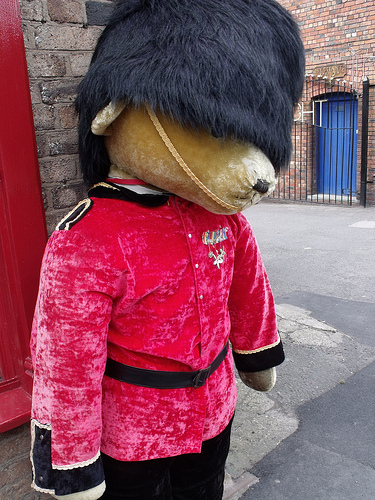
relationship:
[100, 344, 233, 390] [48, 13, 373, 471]
belt on bear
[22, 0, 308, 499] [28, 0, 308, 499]
bear dressed like bear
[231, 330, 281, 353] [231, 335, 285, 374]
trim on cuff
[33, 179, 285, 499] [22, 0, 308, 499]
jacket on bear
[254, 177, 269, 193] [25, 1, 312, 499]
nose on teddy bear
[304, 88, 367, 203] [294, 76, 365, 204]
door behind bars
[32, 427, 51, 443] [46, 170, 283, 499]
snap on cuff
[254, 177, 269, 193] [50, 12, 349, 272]
nose of bear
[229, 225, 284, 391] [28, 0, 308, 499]
arm of bear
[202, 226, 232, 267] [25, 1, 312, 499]
medal on teddy bear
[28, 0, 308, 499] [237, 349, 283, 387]
bear with paws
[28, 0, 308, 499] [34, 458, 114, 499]
bear with paws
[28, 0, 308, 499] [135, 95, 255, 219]
bear with strap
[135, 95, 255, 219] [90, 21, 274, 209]
strap across face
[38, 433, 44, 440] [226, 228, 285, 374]
button on sleeve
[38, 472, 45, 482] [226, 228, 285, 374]
button on sleeve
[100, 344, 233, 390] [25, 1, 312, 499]
belt on teddy bear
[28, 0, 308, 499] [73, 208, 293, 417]
bear in uniform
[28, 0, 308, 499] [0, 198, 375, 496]
bear on pavement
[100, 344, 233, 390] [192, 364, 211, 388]
belt with plastic clasp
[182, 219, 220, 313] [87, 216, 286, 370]
metal buttons on side of cuff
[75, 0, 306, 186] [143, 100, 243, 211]
hat has strap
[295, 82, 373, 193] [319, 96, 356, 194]
fence in front of door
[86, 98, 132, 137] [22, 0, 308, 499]
ear of bear